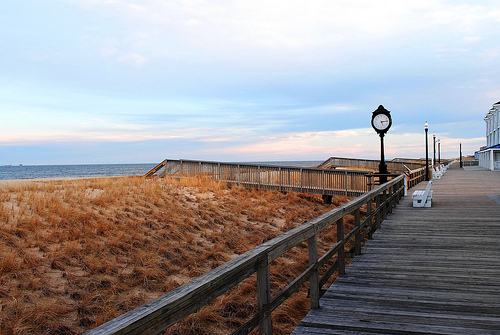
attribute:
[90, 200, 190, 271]
dried grass — dry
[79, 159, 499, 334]
boardwalk — brown, wooden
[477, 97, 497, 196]
building — white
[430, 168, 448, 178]
bench — white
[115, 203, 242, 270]
grass — brown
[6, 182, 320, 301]
field — yellow, grassy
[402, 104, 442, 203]
lamp post — metal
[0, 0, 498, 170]
sky — cloudy, blue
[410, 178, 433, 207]
bench — white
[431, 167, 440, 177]
bench — white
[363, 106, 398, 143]
clock — face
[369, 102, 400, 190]
tower — balck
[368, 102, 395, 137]
clock — is outside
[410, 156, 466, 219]
benches — white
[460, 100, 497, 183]
building — white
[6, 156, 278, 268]
beach — sandy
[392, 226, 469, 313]
slats — wooden 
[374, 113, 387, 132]
clock — face